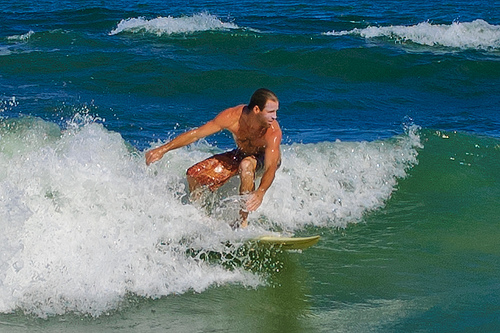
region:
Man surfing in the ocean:
[8, 4, 496, 324]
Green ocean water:
[333, 142, 498, 327]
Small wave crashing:
[12, 107, 483, 315]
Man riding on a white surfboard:
[139, 70, 336, 257]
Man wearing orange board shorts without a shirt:
[137, 67, 329, 274]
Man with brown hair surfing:
[134, 67, 330, 264]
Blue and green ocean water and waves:
[10, 2, 497, 83]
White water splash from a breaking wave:
[3, 100, 144, 325]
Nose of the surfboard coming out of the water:
[255, 217, 335, 266]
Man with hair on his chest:
[220, 74, 297, 168]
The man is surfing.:
[122, 76, 356, 265]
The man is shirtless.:
[132, 90, 309, 197]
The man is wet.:
[146, 74, 310, 238]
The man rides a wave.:
[125, 75, 346, 273]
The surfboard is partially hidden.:
[166, 225, 332, 256]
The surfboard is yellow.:
[221, 224, 331, 264]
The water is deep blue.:
[55, 48, 492, 138]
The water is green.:
[323, 135, 495, 330]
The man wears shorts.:
[170, 141, 285, 193]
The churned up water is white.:
[0, 138, 147, 305]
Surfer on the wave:
[103, 80, 392, 282]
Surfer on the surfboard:
[169, 143, 372, 271]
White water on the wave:
[32, 157, 357, 265]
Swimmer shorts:
[186, 149, 288, 207]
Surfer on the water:
[149, 75, 369, 309]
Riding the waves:
[113, 60, 353, 308]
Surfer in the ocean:
[81, 51, 438, 310]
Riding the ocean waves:
[134, 70, 373, 270]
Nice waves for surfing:
[107, 100, 429, 287]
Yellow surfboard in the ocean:
[226, 209, 323, 266]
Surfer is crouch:
[136, 63, 327, 270]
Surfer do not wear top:
[119, 65, 306, 252]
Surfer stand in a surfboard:
[121, 84, 318, 268]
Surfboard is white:
[169, 214, 331, 260]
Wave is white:
[1, 136, 398, 304]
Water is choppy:
[19, 7, 496, 92]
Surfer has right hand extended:
[130, 84, 305, 256]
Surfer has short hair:
[136, 70, 298, 262]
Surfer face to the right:
[107, 66, 307, 245]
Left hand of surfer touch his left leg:
[129, 68, 302, 253]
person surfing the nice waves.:
[66, 52, 408, 283]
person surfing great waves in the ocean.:
[40, 61, 365, 271]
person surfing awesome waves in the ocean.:
[30, 40, 361, 277]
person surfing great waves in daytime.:
[70, 55, 367, 302]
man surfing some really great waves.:
[95, 55, 400, 285]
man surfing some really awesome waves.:
[62, 50, 397, 290]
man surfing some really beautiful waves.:
[52, 45, 357, 292]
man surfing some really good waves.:
[60, 70, 361, 267]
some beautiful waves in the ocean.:
[30, 100, 135, 297]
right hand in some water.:
[130, 137, 166, 174]